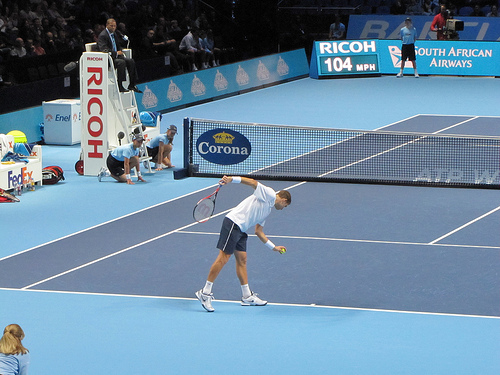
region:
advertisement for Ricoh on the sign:
[314, 35, 377, 51]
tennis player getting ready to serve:
[180, 167, 295, 309]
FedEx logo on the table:
[3, 152, 46, 194]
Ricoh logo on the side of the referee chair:
[74, 15, 156, 181]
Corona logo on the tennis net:
[191, 122, 256, 169]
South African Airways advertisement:
[389, 38, 499, 75]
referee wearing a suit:
[96, 18, 142, 97]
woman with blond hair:
[0, 323, 37, 373]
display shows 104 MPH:
[313, 53, 378, 75]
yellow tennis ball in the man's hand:
[275, 241, 288, 258]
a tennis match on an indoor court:
[4, 13, 498, 366]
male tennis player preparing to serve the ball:
[191, 168, 297, 313]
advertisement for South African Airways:
[414, 42, 495, 74]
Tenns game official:
[81, 12, 146, 94]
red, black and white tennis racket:
[192, 175, 225, 228]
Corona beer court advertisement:
[193, 125, 253, 167]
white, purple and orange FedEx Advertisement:
[3, 153, 47, 193]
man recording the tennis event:
[426, 0, 474, 42]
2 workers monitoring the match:
[91, 120, 188, 181]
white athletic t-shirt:
[223, 185, 278, 242]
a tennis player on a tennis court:
[192, 172, 292, 310]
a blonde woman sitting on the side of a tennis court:
[0, 318, 29, 355]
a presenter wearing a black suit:
[96, 16, 143, 93]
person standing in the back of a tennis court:
[396, 16, 421, 77]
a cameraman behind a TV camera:
[429, 3, 465, 43]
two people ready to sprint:
[96, 127, 180, 187]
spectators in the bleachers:
[1, 1, 496, 79]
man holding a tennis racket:
[189, 173, 229, 222]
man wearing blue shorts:
[215, 216, 249, 253]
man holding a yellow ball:
[275, 240, 287, 255]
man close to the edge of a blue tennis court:
[0, 110, 497, 315]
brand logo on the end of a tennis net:
[181, 116, 248, 173]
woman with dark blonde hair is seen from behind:
[1, 320, 29, 372]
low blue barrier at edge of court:
[2, 47, 309, 142]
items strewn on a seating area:
[0, 133, 42, 203]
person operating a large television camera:
[429, 3, 464, 42]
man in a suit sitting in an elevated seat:
[79, 14, 150, 172]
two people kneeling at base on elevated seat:
[76, 121, 180, 184]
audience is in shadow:
[0, 0, 288, 115]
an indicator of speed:
[315, 51, 382, 73]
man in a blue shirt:
[393, 8, 425, 78]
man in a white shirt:
[193, 161, 297, 328]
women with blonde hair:
[3, 318, 31, 373]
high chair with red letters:
[76, 35, 151, 183]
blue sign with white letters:
[196, 121, 257, 171]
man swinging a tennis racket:
[183, 164, 302, 320]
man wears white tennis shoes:
[183, 161, 305, 325]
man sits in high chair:
[76, 12, 161, 183]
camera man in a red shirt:
[426, 4, 454, 41]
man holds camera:
[426, 8, 466, 40]